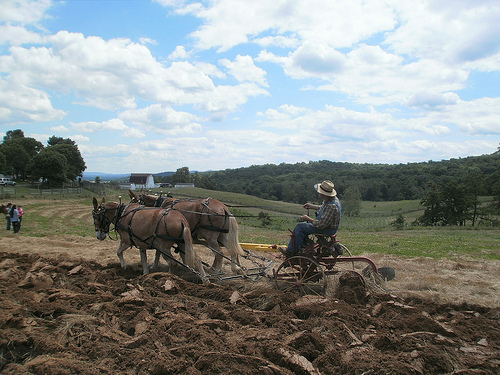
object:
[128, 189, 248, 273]
horse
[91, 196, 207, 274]
horse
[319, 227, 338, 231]
belt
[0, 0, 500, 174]
sky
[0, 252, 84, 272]
furrow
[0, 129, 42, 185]
tree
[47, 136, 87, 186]
tree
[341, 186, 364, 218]
tree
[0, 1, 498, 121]
cloud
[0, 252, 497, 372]
dirt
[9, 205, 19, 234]
people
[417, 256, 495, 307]
straw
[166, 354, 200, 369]
eart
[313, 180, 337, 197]
hat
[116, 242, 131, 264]
legs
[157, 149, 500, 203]
hill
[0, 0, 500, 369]
picture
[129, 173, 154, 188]
buildings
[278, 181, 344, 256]
farmer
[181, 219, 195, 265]
tail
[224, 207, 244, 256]
tail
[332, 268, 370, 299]
plow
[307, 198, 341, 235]
shirt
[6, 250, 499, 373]
field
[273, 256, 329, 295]
wheel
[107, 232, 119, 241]
bridles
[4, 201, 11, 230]
person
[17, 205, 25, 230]
person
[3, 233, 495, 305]
road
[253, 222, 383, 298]
tilling equipment